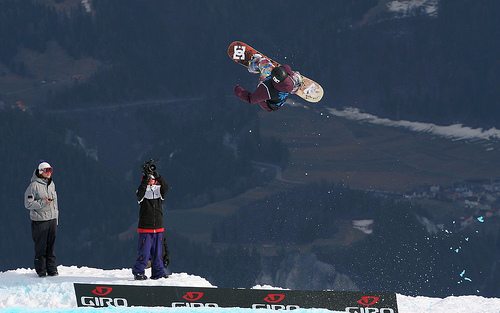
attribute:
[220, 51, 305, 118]
man — snowboarding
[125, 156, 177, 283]
man — standing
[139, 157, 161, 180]
camera — black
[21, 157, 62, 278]
man — standing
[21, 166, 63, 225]
coat — grey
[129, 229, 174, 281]
pants — blue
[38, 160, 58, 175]
goggles — red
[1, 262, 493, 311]
snow — white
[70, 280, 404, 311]
banner — black, red, white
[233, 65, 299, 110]
jacket — red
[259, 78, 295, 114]
vest — black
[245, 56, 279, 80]
pants — tan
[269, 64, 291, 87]
helmet — black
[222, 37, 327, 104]
snowboard — white, red, tan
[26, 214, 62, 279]
pants — black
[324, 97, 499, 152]
snow — white, distant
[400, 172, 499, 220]
town — distant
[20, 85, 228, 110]
road — grey, winding